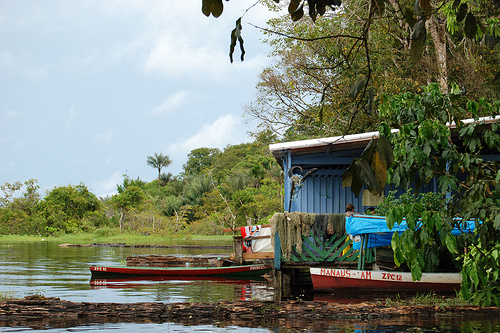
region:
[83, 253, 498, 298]
dinghies are tied up to a house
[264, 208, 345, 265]
fishing nets are hanging on a fence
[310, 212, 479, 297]
a tarp is the canopy for the boat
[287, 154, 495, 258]
the porch of the house on the river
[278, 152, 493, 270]
the river house is wooden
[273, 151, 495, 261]
the house is painted blue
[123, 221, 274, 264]
a dock is on the side of the house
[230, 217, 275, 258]
clothes are hanging to dry on the porch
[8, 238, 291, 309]
the river is calm near the house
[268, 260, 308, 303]
the house is on wooden stilts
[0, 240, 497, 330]
the body of water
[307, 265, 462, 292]
the boat on the water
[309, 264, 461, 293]
the red paint on the boat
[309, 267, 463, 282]
the white paint on the boat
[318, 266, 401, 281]
the letters and numbers on the boat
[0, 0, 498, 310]
the trees around the water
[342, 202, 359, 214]
the person sitting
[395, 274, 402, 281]
the 12 on the boat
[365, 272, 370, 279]
the "M" on the boat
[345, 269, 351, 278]
the "S" on the boat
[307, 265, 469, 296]
a red and white boat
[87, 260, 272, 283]
a red and black boat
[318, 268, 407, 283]
writing on the side of a boat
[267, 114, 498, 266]
a blue wooden building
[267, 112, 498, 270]
a blue boat house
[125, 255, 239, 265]
a wooden dock on a lake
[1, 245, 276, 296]
a rippling lake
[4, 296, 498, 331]
a small shoreline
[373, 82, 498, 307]
leaves of a tree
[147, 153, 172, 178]
a tall palm tree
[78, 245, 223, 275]
boat in water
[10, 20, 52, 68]
white clouds in blue sky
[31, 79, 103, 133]
white clouds in blue sky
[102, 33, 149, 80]
white clouds in blue sky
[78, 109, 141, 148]
white clouds in blue sky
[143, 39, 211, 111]
white clouds in blue sky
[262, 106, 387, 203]
blue shed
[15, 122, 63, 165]
white clouds in blue sky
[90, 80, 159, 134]
white clouds in blue sky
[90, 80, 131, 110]
white clouds in blue sky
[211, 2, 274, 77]
a part of the stem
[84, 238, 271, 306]
a boat in water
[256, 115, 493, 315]
a big room near water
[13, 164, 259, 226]
a group of trees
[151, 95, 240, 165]
white clouds in sky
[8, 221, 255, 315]
a cool view of water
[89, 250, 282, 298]
a boat in water standing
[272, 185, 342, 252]
a clothe inside the room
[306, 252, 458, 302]
a boat under the room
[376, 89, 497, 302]
a part of the trees